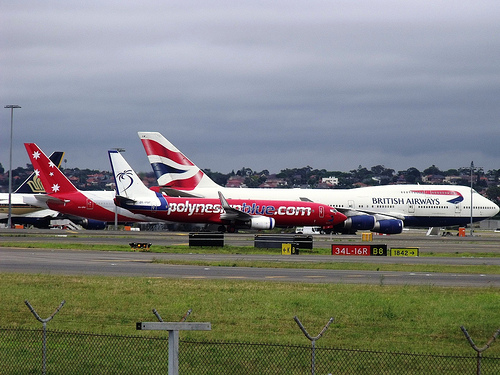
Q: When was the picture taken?
A: Daytime.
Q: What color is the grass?
A: Green.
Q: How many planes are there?
A: Four.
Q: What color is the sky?
A: Gray and blue.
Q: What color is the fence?
A: Gray.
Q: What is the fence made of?
A: Metal.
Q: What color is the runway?
A: Black.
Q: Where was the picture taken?
A: Airport.